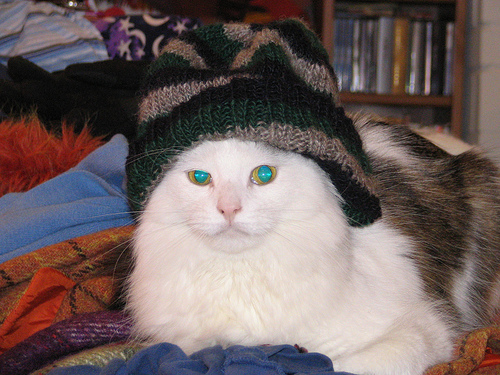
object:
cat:
[123, 108, 500, 375]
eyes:
[247, 165, 278, 188]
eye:
[183, 168, 213, 187]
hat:
[124, 20, 381, 230]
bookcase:
[320, 0, 468, 143]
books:
[374, 17, 394, 92]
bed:
[0, 0, 184, 375]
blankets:
[40, 342, 356, 375]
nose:
[215, 194, 241, 225]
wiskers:
[256, 204, 345, 260]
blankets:
[0, 57, 147, 142]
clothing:
[0, 134, 130, 267]